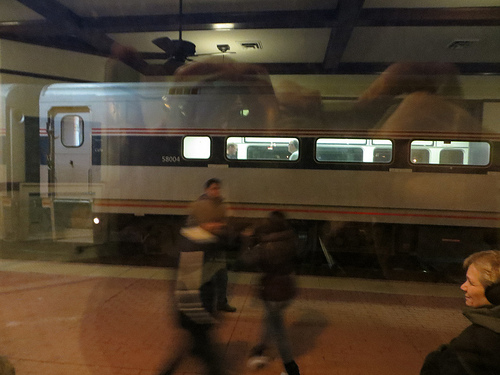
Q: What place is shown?
A: It is a station.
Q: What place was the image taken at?
A: It was taken at the station.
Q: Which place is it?
A: It is a station.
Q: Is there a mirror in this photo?
A: No, there are no mirrors.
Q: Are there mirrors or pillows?
A: No, there are no mirrors or pillows.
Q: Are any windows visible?
A: Yes, there are windows.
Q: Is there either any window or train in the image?
A: Yes, there are windows.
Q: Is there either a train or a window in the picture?
A: Yes, there are windows.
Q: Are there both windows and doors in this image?
A: Yes, there are both windows and a door.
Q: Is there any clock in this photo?
A: No, there are no clocks.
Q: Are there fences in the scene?
A: No, there are no fences.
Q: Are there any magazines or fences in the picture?
A: No, there are no fences or magazines.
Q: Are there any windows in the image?
A: Yes, there are windows.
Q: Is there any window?
A: Yes, there are windows.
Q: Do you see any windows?
A: Yes, there are windows.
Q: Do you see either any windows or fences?
A: Yes, there are windows.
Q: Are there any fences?
A: No, there are no fences.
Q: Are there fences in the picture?
A: No, there are no fences.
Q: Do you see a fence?
A: No, there are no fences.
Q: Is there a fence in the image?
A: No, there are no fences.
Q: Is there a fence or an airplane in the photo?
A: No, there are no fences or airplanes.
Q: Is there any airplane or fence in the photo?
A: No, there are no fences or airplanes.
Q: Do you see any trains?
A: Yes, there is a train.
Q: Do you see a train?
A: Yes, there is a train.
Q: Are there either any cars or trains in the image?
A: Yes, there is a train.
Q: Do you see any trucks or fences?
A: No, there are no fences or trucks.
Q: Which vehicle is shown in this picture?
A: The vehicle is a train.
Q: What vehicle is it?
A: The vehicle is a train.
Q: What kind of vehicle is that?
A: This is a train.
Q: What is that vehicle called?
A: This is a train.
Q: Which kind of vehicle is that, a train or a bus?
A: This is a train.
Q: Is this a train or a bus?
A: This is a train.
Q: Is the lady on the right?
A: Yes, the lady is on the right of the image.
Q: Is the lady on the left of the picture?
A: No, the lady is on the right of the image.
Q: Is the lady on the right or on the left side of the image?
A: The lady is on the right of the image.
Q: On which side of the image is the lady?
A: The lady is on the right of the image.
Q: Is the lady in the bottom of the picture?
A: Yes, the lady is in the bottom of the image.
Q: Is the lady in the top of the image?
A: No, the lady is in the bottom of the image.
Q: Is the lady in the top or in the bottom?
A: The lady is in the bottom of the image.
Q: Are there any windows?
A: Yes, there is a window.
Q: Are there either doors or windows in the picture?
A: Yes, there is a window.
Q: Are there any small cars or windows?
A: Yes, there is a small window.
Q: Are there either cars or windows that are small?
A: Yes, the window is small.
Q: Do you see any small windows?
A: Yes, there is a small window.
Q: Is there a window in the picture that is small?
A: Yes, there is a window that is small.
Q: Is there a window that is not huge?
A: Yes, there is a small window.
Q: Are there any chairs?
A: No, there are no chairs.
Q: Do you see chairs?
A: No, there are no chairs.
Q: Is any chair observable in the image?
A: No, there are no chairs.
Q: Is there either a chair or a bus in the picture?
A: No, there are no chairs or buses.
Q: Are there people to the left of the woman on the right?
A: Yes, there are people to the left of the woman.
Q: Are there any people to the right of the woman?
A: No, the people are to the left of the woman.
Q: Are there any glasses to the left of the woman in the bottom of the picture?
A: No, there are people to the left of the woman.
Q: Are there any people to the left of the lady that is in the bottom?
A: Yes, there are people to the left of the lady.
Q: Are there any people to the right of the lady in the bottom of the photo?
A: No, the people are to the left of the lady.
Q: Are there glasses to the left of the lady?
A: No, there are people to the left of the lady.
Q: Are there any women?
A: Yes, there is a woman.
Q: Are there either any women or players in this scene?
A: Yes, there is a woman.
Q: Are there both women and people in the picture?
A: Yes, there are both a woman and people.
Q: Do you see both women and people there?
A: Yes, there are both a woman and people.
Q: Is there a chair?
A: No, there are no chairs.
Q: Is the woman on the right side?
A: Yes, the woman is on the right of the image.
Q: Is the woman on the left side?
A: No, the woman is on the right of the image.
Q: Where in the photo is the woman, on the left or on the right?
A: The woman is on the right of the image.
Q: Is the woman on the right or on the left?
A: The woman is on the right of the image.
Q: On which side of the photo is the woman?
A: The woman is on the right of the image.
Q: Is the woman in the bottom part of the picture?
A: Yes, the woman is in the bottom of the image.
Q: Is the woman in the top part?
A: No, the woman is in the bottom of the image.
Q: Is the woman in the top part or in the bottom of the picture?
A: The woman is in the bottom of the image.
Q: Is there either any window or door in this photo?
A: Yes, there are windows.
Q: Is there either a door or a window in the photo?
A: Yes, there are windows.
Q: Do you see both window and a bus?
A: No, there are windows but no buses.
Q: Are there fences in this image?
A: No, there are no fences.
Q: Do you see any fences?
A: No, there are no fences.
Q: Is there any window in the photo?
A: Yes, there is a window.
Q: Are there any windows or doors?
A: Yes, there is a window.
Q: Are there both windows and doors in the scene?
A: Yes, there are both a window and a door.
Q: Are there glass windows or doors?
A: Yes, there is a glass window.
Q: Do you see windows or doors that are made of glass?
A: Yes, the window is made of glass.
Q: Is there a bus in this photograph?
A: No, there are no buses.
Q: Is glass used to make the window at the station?
A: Yes, the window is made of glass.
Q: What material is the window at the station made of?
A: The window is made of glass.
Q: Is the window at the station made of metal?
A: No, the window is made of glass.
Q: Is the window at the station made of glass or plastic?
A: The window is made of glass.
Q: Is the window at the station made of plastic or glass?
A: The window is made of glass.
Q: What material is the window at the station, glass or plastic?
A: The window is made of glass.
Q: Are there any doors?
A: Yes, there is a door.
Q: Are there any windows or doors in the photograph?
A: Yes, there is a door.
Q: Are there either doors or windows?
A: Yes, there is a door.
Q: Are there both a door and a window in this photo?
A: Yes, there are both a door and a window.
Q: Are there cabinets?
A: No, there are no cabinets.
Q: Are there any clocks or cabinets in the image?
A: No, there are no cabinets or clocks.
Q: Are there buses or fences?
A: No, there are no fences or buses.